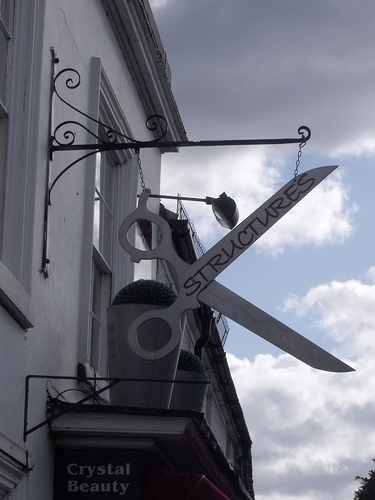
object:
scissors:
[118, 165, 357, 373]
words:
[66, 464, 80, 482]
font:
[182, 173, 315, 297]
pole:
[52, 125, 312, 153]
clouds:
[148, 0, 374, 156]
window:
[80, 55, 116, 399]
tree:
[352, 458, 375, 499]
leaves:
[352, 467, 374, 500]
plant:
[110, 279, 178, 305]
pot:
[106, 302, 187, 416]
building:
[1, 1, 189, 499]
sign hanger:
[40, 44, 311, 278]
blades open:
[199, 165, 358, 372]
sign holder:
[25, 366, 212, 440]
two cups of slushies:
[105, 280, 210, 415]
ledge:
[48, 400, 259, 500]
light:
[93, 144, 101, 257]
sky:
[145, 0, 375, 499]